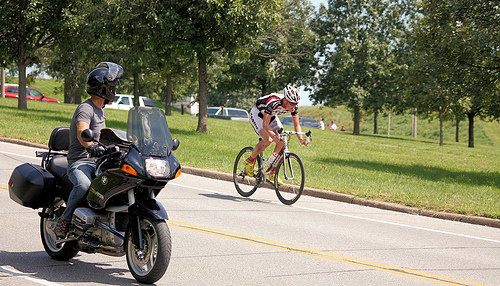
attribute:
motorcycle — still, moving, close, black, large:
[44, 127, 166, 263]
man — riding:
[61, 57, 126, 167]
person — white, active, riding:
[248, 86, 306, 138]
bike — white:
[237, 150, 315, 199]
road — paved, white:
[237, 207, 393, 273]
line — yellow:
[239, 231, 306, 263]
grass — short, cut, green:
[355, 144, 448, 209]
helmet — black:
[73, 61, 133, 100]